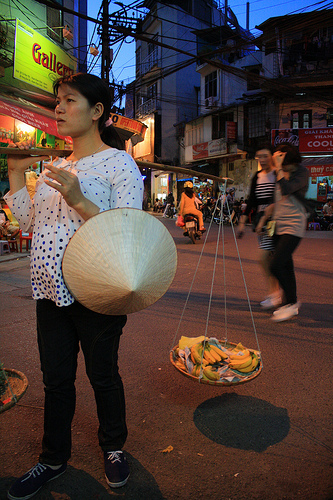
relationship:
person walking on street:
[256, 143, 308, 322] [1, 218, 332, 499]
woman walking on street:
[6, 73, 143, 498] [1, 218, 332, 499]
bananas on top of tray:
[189, 338, 260, 382] [168, 340, 264, 385]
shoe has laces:
[102, 449, 131, 489] [106, 451, 124, 465]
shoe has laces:
[5, 464, 69, 500] [20, 459, 47, 482]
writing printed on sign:
[32, 43, 74, 80] [13, 19, 79, 96]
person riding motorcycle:
[176, 181, 206, 233] [182, 214, 201, 246]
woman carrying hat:
[6, 73, 143, 498] [60, 207, 179, 316]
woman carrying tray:
[6, 73, 143, 498] [168, 340, 264, 385]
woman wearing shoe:
[6, 73, 143, 498] [102, 449, 131, 489]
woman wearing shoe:
[6, 73, 143, 498] [5, 464, 69, 500]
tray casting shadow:
[168, 340, 264, 385] [191, 394, 290, 452]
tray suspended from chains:
[168, 340, 264, 385] [170, 179, 264, 383]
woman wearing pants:
[6, 73, 143, 498] [35, 299, 127, 466]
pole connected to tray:
[2, 148, 235, 186] [168, 340, 264, 385]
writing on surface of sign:
[32, 43, 74, 80] [13, 19, 79, 96]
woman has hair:
[6, 73, 143, 498] [53, 73, 125, 151]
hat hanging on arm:
[60, 207, 179, 316] [42, 153, 144, 221]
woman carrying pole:
[6, 73, 143, 498] [2, 148, 235, 186]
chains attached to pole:
[170, 179, 264, 383] [2, 148, 235, 186]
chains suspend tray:
[170, 179, 264, 383] [168, 340, 264, 385]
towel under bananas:
[178, 338, 264, 381] [189, 338, 260, 382]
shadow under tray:
[191, 394, 290, 452] [168, 340, 264, 385]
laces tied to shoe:
[20, 459, 47, 482] [5, 464, 69, 500]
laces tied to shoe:
[106, 451, 124, 465] [102, 449, 131, 489]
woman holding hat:
[6, 73, 143, 498] [60, 207, 179, 316]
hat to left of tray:
[60, 207, 179, 316] [168, 340, 264, 385]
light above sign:
[35, 27, 75, 43] [13, 19, 79, 96]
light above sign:
[64, 44, 98, 57] [13, 19, 79, 96]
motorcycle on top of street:
[182, 214, 201, 246] [1, 218, 332, 499]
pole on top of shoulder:
[2, 148, 235, 186] [46, 156, 66, 168]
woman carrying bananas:
[6, 73, 143, 498] [189, 338, 260, 382]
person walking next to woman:
[256, 143, 308, 322] [234, 142, 283, 308]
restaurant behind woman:
[1, 85, 73, 254] [6, 73, 143, 498]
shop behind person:
[269, 125, 333, 230] [256, 143, 308, 322]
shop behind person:
[180, 138, 264, 222] [176, 181, 206, 233]